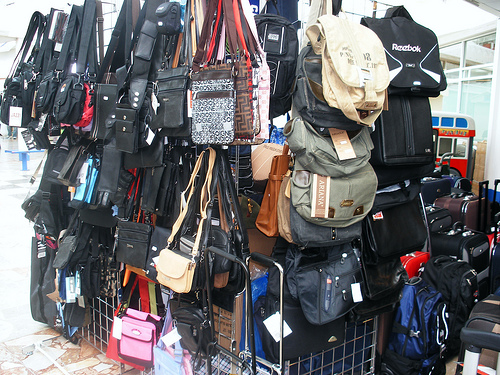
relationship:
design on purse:
[186, 63, 240, 147] [187, 59, 239, 148]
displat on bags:
[304, 322, 374, 372] [328, 330, 369, 364]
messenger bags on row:
[263, 2, 402, 340] [266, 1, 396, 350]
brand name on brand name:
[388, 41, 424, 54] [388, 41, 424, 54]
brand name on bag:
[388, 41, 419, 54] [363, 2, 451, 99]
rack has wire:
[40, 182, 406, 372] [92, 295, 114, 338]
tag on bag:
[261, 310, 292, 343] [256, 300, 319, 364]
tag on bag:
[345, 280, 365, 304] [276, 245, 374, 332]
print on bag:
[275, 155, 361, 280] [253, 104, 414, 262]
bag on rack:
[290, 155, 379, 227] [24, 49, 287, 301]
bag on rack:
[261, 107, 392, 281] [254, 3, 478, 203]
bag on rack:
[290, 155, 379, 227] [381, 70, 479, 290]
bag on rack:
[187, 57, 240, 139] [412, 33, 468, 225]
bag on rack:
[190, 70, 236, 146] [364, 44, 472, 307]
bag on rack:
[290, 155, 379, 227] [379, 29, 480, 179]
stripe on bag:
[242, 237, 311, 366] [300, 144, 383, 301]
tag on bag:
[243, 282, 316, 350] [128, 164, 321, 338]